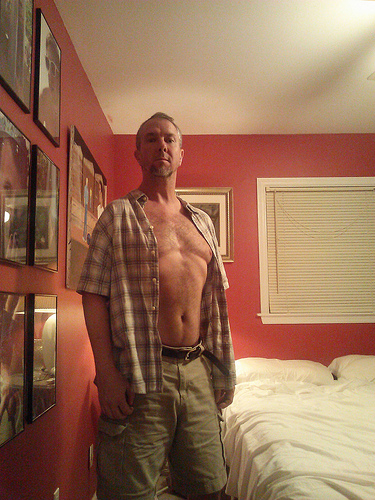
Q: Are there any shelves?
A: No, there are no shelves.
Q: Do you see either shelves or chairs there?
A: No, there are no shelves or chairs.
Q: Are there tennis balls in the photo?
A: No, there are no tennis balls.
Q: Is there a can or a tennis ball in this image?
A: No, there are no tennis balls or cans.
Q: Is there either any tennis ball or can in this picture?
A: No, there are no tennis balls or cans.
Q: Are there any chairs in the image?
A: No, there are no chairs.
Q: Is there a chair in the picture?
A: No, there are no chairs.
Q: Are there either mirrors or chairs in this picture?
A: No, there are no chairs or mirrors.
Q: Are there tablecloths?
A: No, there are no tablecloths.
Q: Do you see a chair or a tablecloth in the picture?
A: No, there are no tablecloths or chairs.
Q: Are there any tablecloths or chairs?
A: No, there are no tablecloths or chairs.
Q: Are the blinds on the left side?
A: No, the blinds are on the right of the image.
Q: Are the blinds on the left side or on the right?
A: The blinds are on the right of the image.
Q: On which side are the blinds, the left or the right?
A: The blinds are on the right of the image.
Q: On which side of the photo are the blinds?
A: The blinds are on the right of the image.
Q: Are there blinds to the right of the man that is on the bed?
A: Yes, there are blinds to the right of the man.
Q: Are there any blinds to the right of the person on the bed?
A: Yes, there are blinds to the right of the man.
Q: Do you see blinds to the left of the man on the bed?
A: No, the blinds are to the right of the man.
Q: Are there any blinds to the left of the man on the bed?
A: No, the blinds are to the right of the man.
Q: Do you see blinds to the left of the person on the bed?
A: No, the blinds are to the right of the man.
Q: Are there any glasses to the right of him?
A: No, there are blinds to the right of the man.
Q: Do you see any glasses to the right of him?
A: No, there are blinds to the right of the man.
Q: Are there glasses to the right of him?
A: No, there are blinds to the right of the man.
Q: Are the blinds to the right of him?
A: Yes, the blinds are to the right of the man.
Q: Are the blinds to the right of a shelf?
A: No, the blinds are to the right of the man.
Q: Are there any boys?
A: No, there are no boys.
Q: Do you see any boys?
A: No, there are no boys.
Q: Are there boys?
A: No, there are no boys.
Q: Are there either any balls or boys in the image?
A: No, there are no boys or balls.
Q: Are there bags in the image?
A: No, there are no bags.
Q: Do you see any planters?
A: No, there are no planters.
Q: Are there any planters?
A: No, there are no planters.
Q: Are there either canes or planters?
A: No, there are no planters or canes.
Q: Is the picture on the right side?
A: No, the picture is on the left of the image.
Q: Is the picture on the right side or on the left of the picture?
A: The picture is on the left of the image.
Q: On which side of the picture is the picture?
A: The picture is on the left of the image.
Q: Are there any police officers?
A: No, there are no police officers.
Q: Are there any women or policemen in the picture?
A: No, there are no policemen or women.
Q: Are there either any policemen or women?
A: No, there are no policemen or women.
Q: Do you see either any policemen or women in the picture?
A: No, there are no policemen or women.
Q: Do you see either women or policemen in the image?
A: No, there are no policemen or women.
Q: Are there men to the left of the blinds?
A: Yes, there is a man to the left of the blinds.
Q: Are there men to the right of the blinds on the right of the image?
A: No, the man is to the left of the blinds.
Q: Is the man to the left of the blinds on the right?
A: Yes, the man is to the left of the blinds.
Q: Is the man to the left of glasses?
A: No, the man is to the left of the blinds.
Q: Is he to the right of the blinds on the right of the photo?
A: No, the man is to the left of the blinds.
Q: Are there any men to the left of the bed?
A: Yes, there is a man to the left of the bed.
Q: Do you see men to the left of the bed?
A: Yes, there is a man to the left of the bed.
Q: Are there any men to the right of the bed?
A: No, the man is to the left of the bed.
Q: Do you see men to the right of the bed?
A: No, the man is to the left of the bed.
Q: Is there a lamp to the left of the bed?
A: No, there is a man to the left of the bed.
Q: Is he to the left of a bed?
A: Yes, the man is to the left of a bed.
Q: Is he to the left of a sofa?
A: No, the man is to the left of a bed.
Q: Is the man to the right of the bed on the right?
A: No, the man is to the left of the bed.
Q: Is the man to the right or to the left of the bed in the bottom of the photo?
A: The man is to the left of the bed.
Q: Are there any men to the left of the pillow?
A: Yes, there is a man to the left of the pillow.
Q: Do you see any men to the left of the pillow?
A: Yes, there is a man to the left of the pillow.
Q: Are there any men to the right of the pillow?
A: No, the man is to the left of the pillow.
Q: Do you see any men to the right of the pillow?
A: No, the man is to the left of the pillow.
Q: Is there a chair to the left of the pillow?
A: No, there is a man to the left of the pillow.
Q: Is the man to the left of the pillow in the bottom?
A: Yes, the man is to the left of the pillow.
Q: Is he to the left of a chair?
A: No, the man is to the left of the pillow.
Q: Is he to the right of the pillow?
A: No, the man is to the left of the pillow.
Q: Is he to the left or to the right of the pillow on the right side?
A: The man is to the left of the pillow.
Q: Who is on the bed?
A: The man is on the bed.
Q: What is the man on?
A: The man is on the bed.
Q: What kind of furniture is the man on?
A: The man is on the bed.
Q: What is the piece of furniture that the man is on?
A: The piece of furniture is a bed.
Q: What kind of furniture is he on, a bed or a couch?
A: The man is on a bed.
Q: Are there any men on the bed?
A: Yes, there is a man on the bed.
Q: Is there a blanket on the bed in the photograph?
A: No, there is a man on the bed.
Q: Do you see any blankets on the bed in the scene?
A: No, there is a man on the bed.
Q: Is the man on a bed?
A: Yes, the man is on a bed.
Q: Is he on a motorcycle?
A: No, the man is on a bed.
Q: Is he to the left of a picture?
A: No, the man is to the right of a picture.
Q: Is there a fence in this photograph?
A: No, there are no fences.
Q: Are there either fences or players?
A: No, there are no fences or players.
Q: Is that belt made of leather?
A: Yes, the belt is made of leather.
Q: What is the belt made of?
A: The belt is made of leather.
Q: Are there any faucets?
A: No, there are no faucets.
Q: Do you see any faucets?
A: No, there are no faucets.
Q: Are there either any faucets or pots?
A: No, there are no faucets or pots.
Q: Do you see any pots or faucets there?
A: No, there are no faucets or pots.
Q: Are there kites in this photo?
A: No, there are no kites.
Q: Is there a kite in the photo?
A: No, there are no kites.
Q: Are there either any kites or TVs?
A: No, there are no kites or tvs.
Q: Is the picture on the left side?
A: Yes, the picture is on the left of the image.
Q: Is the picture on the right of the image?
A: No, the picture is on the left of the image.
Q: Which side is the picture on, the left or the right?
A: The picture is on the left of the image.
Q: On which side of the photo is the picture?
A: The picture is on the left of the image.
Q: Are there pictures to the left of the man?
A: Yes, there is a picture to the left of the man.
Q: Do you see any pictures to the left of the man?
A: Yes, there is a picture to the left of the man.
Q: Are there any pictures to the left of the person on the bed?
A: Yes, there is a picture to the left of the man.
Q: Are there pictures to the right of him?
A: No, the picture is to the left of the man.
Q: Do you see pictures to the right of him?
A: No, the picture is to the left of the man.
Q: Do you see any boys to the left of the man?
A: No, there is a picture to the left of the man.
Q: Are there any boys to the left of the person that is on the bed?
A: No, there is a picture to the left of the man.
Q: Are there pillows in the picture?
A: Yes, there is a pillow.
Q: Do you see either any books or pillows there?
A: Yes, there is a pillow.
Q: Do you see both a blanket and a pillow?
A: No, there is a pillow but no blankets.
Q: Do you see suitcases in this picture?
A: No, there are no suitcases.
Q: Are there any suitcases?
A: No, there are no suitcases.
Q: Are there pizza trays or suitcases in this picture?
A: No, there are no suitcases or pizza trays.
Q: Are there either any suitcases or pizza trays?
A: No, there are no suitcases or pizza trays.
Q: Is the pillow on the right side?
A: Yes, the pillow is on the right of the image.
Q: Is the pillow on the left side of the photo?
A: No, the pillow is on the right of the image.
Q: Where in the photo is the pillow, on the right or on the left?
A: The pillow is on the right of the image.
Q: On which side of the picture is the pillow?
A: The pillow is on the right of the image.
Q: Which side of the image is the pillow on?
A: The pillow is on the right of the image.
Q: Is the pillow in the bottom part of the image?
A: Yes, the pillow is in the bottom of the image.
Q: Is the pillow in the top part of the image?
A: No, the pillow is in the bottom of the image.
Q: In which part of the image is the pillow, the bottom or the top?
A: The pillow is in the bottom of the image.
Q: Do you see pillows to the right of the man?
A: Yes, there is a pillow to the right of the man.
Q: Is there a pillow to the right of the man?
A: Yes, there is a pillow to the right of the man.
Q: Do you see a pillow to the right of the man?
A: Yes, there is a pillow to the right of the man.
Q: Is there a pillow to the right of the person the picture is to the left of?
A: Yes, there is a pillow to the right of the man.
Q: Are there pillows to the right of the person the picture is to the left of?
A: Yes, there is a pillow to the right of the man.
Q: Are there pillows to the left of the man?
A: No, the pillow is to the right of the man.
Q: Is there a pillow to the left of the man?
A: No, the pillow is to the right of the man.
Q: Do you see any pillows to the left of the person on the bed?
A: No, the pillow is to the right of the man.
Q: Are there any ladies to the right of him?
A: No, there is a pillow to the right of the man.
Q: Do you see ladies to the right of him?
A: No, there is a pillow to the right of the man.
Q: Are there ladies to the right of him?
A: No, there is a pillow to the right of the man.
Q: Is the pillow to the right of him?
A: Yes, the pillow is to the right of a man.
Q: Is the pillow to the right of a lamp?
A: No, the pillow is to the right of a man.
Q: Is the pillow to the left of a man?
A: No, the pillow is to the right of a man.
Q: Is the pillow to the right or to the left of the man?
A: The pillow is to the right of the man.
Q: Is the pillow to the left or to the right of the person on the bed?
A: The pillow is to the right of the man.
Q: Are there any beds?
A: Yes, there is a bed.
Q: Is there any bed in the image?
A: Yes, there is a bed.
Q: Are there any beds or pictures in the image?
A: Yes, there is a bed.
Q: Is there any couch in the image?
A: No, there are no couches.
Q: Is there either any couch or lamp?
A: No, there are no couches or lamps.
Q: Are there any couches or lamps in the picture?
A: No, there are no couches or lamps.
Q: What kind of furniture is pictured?
A: The furniture is a bed.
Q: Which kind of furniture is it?
A: The piece of furniture is a bed.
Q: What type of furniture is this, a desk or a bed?
A: This is a bed.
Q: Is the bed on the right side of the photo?
A: Yes, the bed is on the right of the image.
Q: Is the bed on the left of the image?
A: No, the bed is on the right of the image.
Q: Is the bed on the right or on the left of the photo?
A: The bed is on the right of the image.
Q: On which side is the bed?
A: The bed is on the right of the image.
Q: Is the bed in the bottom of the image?
A: Yes, the bed is in the bottom of the image.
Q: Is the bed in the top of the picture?
A: No, the bed is in the bottom of the image.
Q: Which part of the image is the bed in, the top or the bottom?
A: The bed is in the bottom of the image.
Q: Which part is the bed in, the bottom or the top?
A: The bed is in the bottom of the image.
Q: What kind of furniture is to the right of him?
A: The piece of furniture is a bed.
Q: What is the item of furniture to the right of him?
A: The piece of furniture is a bed.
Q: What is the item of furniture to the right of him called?
A: The piece of furniture is a bed.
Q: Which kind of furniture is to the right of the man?
A: The piece of furniture is a bed.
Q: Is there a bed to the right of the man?
A: Yes, there is a bed to the right of the man.